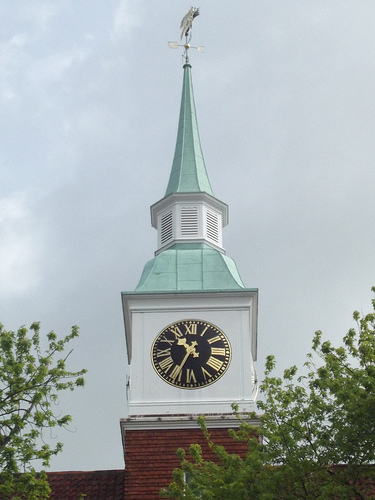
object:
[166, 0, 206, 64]
weather vane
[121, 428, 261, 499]
brick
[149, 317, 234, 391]
clock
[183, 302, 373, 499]
tree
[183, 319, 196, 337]
roman numerals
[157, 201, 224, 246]
air vents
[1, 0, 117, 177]
sky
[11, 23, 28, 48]
clouds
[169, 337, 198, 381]
hands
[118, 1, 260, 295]
top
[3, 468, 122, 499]
building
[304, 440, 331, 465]
branches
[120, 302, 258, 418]
wall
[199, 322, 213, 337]
gold marks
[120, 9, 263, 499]
tower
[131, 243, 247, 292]
shingles